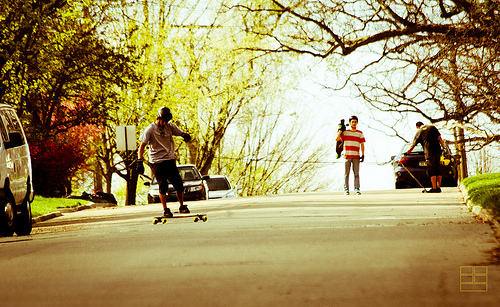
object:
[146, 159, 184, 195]
shorts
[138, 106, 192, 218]
man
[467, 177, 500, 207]
grass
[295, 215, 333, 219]
line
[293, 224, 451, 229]
line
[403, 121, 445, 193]
man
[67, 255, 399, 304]
road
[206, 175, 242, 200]
car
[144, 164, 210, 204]
car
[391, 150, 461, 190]
car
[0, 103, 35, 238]
car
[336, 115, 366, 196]
man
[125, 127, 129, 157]
pole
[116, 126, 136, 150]
sign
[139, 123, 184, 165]
skater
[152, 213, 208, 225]
skateboard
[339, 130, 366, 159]
shirt